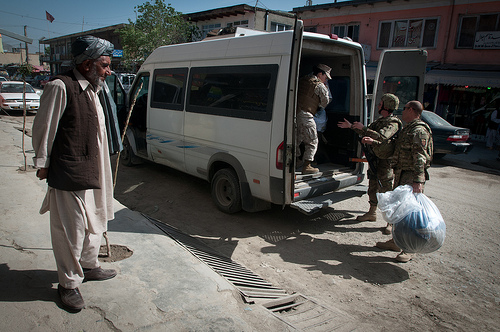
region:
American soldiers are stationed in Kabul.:
[15, 17, 486, 324]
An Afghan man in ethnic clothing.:
[40, 37, 134, 309]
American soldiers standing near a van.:
[123, 27, 445, 268]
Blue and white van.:
[112, 37, 332, 201]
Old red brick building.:
[357, 3, 498, 68]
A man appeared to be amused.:
[10, 31, 127, 316]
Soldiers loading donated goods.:
[292, 52, 450, 255]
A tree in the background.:
[120, 0, 202, 42]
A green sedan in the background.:
[432, 110, 472, 171]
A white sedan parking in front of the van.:
[2, 77, 42, 112]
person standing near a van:
[377, 95, 446, 257]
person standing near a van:
[27, 35, 132, 314]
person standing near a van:
[334, 87, 411, 233]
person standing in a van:
[286, 58, 349, 185]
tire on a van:
[207, 163, 251, 215]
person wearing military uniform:
[379, 97, 446, 266]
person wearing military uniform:
[335, 89, 410, 234]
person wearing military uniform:
[282, 60, 344, 190]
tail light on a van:
[270, 138, 290, 180]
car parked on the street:
[412, 104, 479, 169]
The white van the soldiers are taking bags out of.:
[108, 40, 373, 212]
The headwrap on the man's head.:
[71, 30, 106, 63]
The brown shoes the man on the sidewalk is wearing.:
[55, 253, 115, 308]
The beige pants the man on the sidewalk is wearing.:
[44, 178, 99, 289]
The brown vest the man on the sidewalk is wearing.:
[55, 69, 106, 199]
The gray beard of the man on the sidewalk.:
[91, 62, 101, 85]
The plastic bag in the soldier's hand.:
[384, 180, 441, 250]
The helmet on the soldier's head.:
[371, 92, 398, 114]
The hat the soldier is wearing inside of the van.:
[316, 60, 331, 80]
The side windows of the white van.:
[148, 63, 276, 116]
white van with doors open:
[112, 28, 434, 215]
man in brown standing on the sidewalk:
[30, 33, 120, 315]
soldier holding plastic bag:
[360, 99, 450, 264]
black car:
[420, 106, 473, 163]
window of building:
[375, 15, 442, 52]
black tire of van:
[206, 167, 246, 217]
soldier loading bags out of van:
[290, 60, 335, 179]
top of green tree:
[112, 0, 209, 72]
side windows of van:
[150, 65, 276, 118]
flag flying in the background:
[43, 9, 55, 23]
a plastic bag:
[368, 173, 454, 258]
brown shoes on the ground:
[49, 261, 122, 313]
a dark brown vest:
[51, 70, 126, 188]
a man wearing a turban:
[72, 35, 119, 70]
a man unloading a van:
[286, 48, 359, 186]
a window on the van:
[152, 62, 276, 124]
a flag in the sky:
[40, 7, 56, 27]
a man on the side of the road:
[33, 25, 135, 319]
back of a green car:
[421, 108, 484, 160]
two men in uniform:
[348, 88, 440, 244]